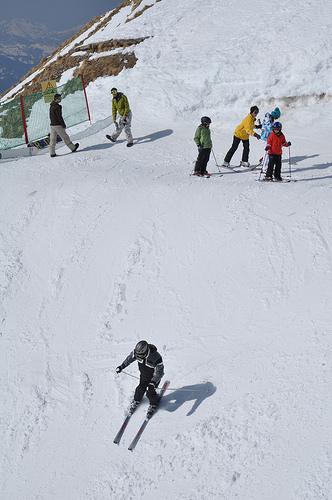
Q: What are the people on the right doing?
A: Skiing.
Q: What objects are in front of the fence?
A: Snowboards.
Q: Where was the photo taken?
A: At a ski slope.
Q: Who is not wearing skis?
A: The two people on the left.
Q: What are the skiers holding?
A: Ski poles.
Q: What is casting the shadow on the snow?
A: A skier.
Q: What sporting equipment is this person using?
A: Skiing equipment.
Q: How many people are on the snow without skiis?
A: Two.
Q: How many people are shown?
A: 7.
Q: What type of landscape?
A: Hill.